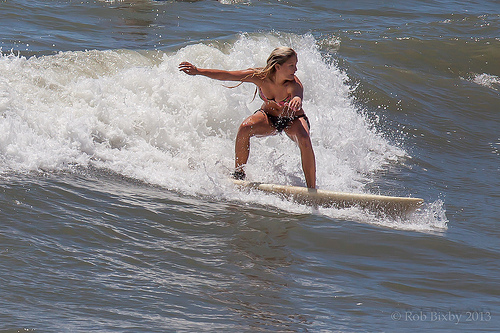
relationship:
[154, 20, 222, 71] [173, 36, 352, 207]
sun reflecting girl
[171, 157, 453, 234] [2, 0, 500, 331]
surfboard on calm water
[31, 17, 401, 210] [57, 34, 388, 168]
water spray from waves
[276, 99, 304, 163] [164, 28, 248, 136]
water dripping from hand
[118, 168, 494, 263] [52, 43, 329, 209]
water calming after wave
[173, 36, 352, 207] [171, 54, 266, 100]
girl using her woman's arm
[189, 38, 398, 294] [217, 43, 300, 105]
girl with blond hair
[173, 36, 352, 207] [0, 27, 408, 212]
girl in foamy wave